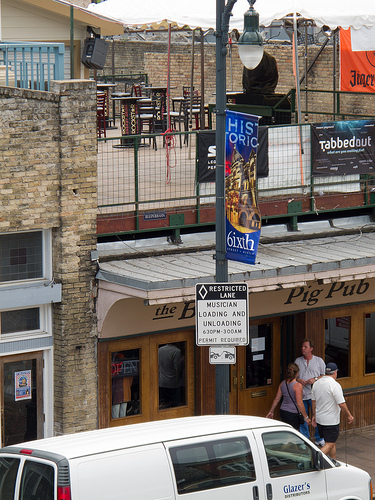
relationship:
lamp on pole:
[234, 0, 263, 75] [215, 0, 232, 414]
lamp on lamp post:
[234, 0, 263, 75] [212, 0, 231, 415]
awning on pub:
[96, 215, 374, 338] [87, 227, 372, 446]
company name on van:
[283, 480, 313, 498] [9, 412, 365, 498]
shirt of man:
[310, 375, 346, 426] [311, 361, 354, 460]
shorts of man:
[318, 421, 339, 443] [311, 361, 354, 460]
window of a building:
[3, 298, 43, 339] [3, 62, 101, 451]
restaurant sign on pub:
[281, 278, 368, 307] [93, 124, 374, 458]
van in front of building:
[9, 412, 365, 498] [89, 119, 374, 438]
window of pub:
[104, 341, 145, 421] [87, 227, 372, 446]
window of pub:
[151, 333, 190, 414] [87, 227, 372, 446]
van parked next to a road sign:
[9, 412, 365, 498] [194, 282, 249, 364]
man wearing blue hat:
[311, 361, 354, 460] [324, 360, 342, 374]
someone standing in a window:
[112, 368, 135, 417] [111, 347, 146, 416]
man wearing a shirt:
[306, 361, 356, 465] [308, 373, 343, 426]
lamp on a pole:
[216, 7, 293, 99] [214, 1, 250, 417]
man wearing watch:
[291, 333, 330, 446] [312, 374, 319, 381]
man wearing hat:
[311, 361, 354, 460] [324, 360, 336, 370]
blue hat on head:
[326, 362, 340, 372] [321, 358, 341, 381]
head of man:
[321, 358, 341, 381] [312, 362, 352, 450]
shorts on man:
[313, 418, 343, 443] [309, 354, 341, 427]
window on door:
[246, 321, 271, 389] [225, 307, 324, 445]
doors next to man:
[198, 327, 290, 423] [290, 338, 331, 452]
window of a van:
[262, 432, 307, 472] [9, 412, 365, 498]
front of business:
[102, 237, 373, 431] [92, 251, 373, 436]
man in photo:
[311, 361, 354, 460] [2, 6, 374, 498]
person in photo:
[274, 364, 308, 426] [2, 6, 374, 498]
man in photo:
[293, 339, 326, 447] [2, 6, 374, 498]